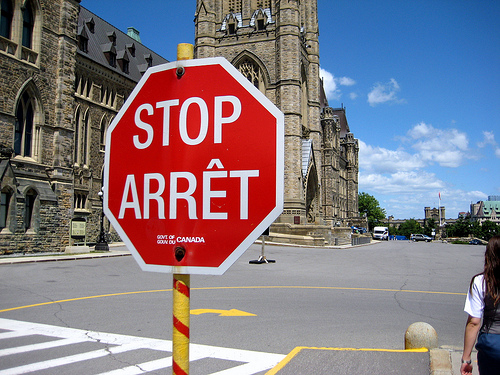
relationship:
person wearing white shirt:
[455, 234, 495, 374] [460, 269, 490, 324]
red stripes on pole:
[151, 271, 209, 368] [144, 245, 254, 372]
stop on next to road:
[130, 90, 245, 149] [0, 238, 500, 373]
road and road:
[0, 238, 500, 373] [0, 238, 500, 373]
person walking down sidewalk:
[455, 234, 499, 375] [357, 343, 489, 370]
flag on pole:
[432, 189, 446, 201] [435, 191, 444, 231]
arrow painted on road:
[187, 305, 257, 317] [0, 238, 500, 373]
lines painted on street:
[0, 314, 283, 374] [64, 233, 456, 373]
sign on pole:
[100, 56, 284, 277] [168, 274, 205, 369]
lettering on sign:
[134, 91, 254, 241] [84, 46, 338, 310]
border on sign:
[138, 56, 234, 71] [100, 56, 284, 277]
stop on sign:
[127, 102, 240, 149] [82, 49, 334, 273]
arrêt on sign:
[115, 167, 256, 233] [82, 49, 334, 273]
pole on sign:
[155, 254, 203, 356] [79, 34, 284, 228]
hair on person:
[480, 235, 498, 275] [460, 244, 498, 363]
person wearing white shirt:
[455, 234, 495, 374] [466, 270, 496, 317]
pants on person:
[476, 333, 498, 373] [456, 249, 496, 373]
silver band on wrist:
[457, 352, 477, 363] [441, 346, 474, 371]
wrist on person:
[441, 346, 474, 371] [459, 231, 497, 366]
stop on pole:
[130, 90, 245, 149] [146, 257, 263, 373]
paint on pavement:
[0, 315, 282, 373] [3, 235, 498, 373]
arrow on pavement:
[187, 308, 257, 317] [3, 235, 498, 373]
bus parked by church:
[372, 226, 388, 240] [1, 0, 373, 262]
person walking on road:
[455, 234, 499, 375] [0, 238, 500, 373]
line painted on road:
[0, 282, 470, 316] [0, 238, 500, 373]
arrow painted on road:
[187, 308, 257, 317] [0, 238, 500, 373]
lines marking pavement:
[0, 314, 283, 374] [9, 234, 394, 372]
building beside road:
[198, 3, 371, 243] [0, 238, 500, 373]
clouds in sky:
[371, 148, 441, 171] [410, 73, 491, 126]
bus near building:
[372, 226, 388, 240] [322, 107, 371, 244]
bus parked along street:
[373, 224, 387, 240] [311, 252, 469, 292]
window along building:
[12, 85, 58, 162] [0, 1, 73, 257]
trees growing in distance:
[358, 190, 383, 224] [30, 254, 494, 375]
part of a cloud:
[337, 55, 485, 261] [362, 117, 473, 193]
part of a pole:
[115, 146, 236, 344] [170, 272, 193, 374]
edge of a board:
[245, 315, 457, 375] [117, 206, 254, 285]